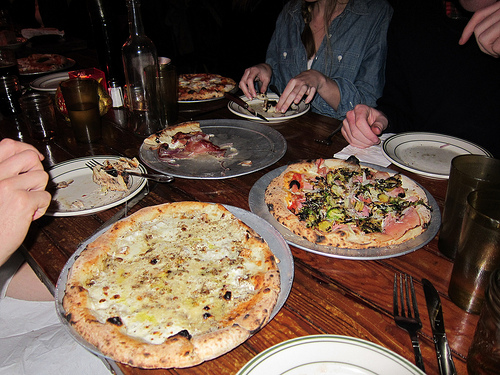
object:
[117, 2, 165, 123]
bottle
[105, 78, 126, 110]
salt shaker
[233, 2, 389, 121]
woman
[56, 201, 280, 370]
pizza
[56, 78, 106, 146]
cup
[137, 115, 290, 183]
pan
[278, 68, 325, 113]
hand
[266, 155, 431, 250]
pizza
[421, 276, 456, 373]
butter knife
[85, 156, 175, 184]
fork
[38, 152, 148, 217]
plate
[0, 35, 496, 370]
table